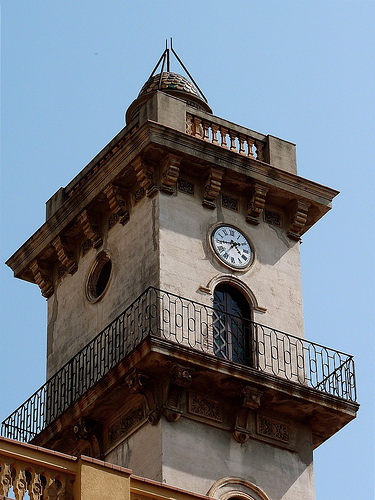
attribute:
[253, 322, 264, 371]
bar — metal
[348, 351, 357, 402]
bar — metal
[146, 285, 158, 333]
bar — metal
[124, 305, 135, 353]
bar — metal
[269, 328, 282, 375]
bar — metal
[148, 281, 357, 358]
metal — bar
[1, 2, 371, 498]
sky — clear, blue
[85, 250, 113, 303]
window — round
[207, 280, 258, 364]
doorway — arched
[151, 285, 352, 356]
bar — metal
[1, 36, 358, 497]
tower — Large, concrete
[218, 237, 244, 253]
hands — black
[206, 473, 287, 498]
doorway — arched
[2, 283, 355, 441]
fence — metal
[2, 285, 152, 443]
railing — Balcony, metal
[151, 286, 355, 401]
railing — Balcony, metal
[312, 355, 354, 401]
railing — Balcony, metal